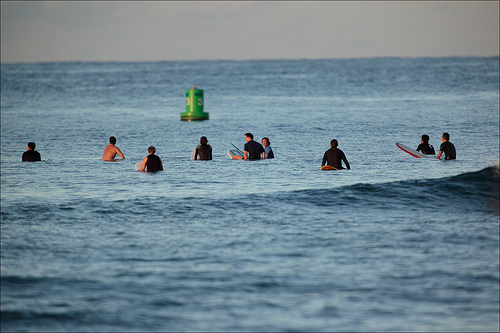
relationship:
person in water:
[137, 145, 166, 173] [1, 57, 500, 333]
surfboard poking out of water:
[393, 140, 423, 158] [15, 192, 490, 321]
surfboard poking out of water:
[319, 164, 336, 171] [15, 192, 490, 321]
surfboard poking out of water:
[227, 147, 244, 161] [15, 192, 490, 321]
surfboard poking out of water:
[131, 158, 146, 171] [15, 192, 490, 321]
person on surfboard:
[320, 136, 352, 168] [319, 164, 336, 171]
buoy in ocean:
[163, 75, 218, 135] [3, 55, 497, 332]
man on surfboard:
[417, 133, 434, 157] [393, 140, 423, 158]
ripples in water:
[187, 205, 260, 256] [1, 57, 498, 323]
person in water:
[234, 128, 264, 161] [4, 162, 498, 330]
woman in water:
[258, 135, 276, 157] [4, 162, 498, 330]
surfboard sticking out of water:
[393, 140, 423, 158] [1, 57, 498, 323]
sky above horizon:
[160, 4, 260, 41] [0, 52, 499, 64]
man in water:
[23, 134, 43, 164] [1, 57, 498, 323]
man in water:
[189, 129, 221, 176] [167, 159, 288, 230]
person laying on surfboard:
[234, 128, 264, 161] [227, 147, 244, 161]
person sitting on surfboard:
[320, 136, 352, 168] [319, 164, 336, 171]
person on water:
[320, 136, 352, 168] [195, 179, 355, 252]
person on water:
[234, 128, 260, 161] [195, 179, 355, 252]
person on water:
[431, 124, 464, 166] [195, 179, 355, 252]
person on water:
[131, 148, 172, 174] [195, 179, 355, 252]